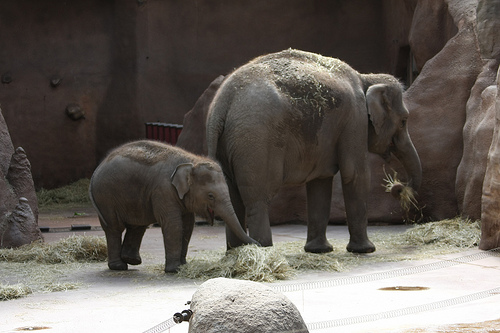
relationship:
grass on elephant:
[270, 52, 343, 105] [224, 44, 402, 151]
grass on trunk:
[270, 52, 343, 105] [380, 169, 423, 211]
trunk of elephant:
[380, 169, 423, 211] [224, 44, 402, 151]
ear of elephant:
[178, 164, 207, 190] [224, 44, 402, 151]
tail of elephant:
[202, 110, 250, 166] [224, 44, 402, 151]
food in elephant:
[201, 238, 292, 275] [224, 44, 402, 151]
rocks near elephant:
[414, 6, 496, 131] [224, 44, 402, 151]